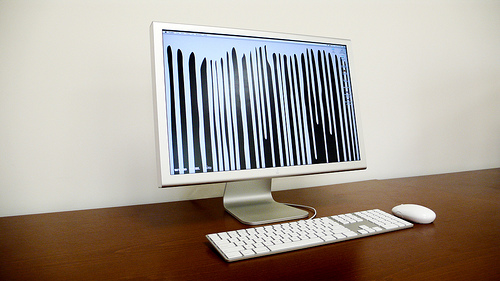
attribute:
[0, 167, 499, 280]
desk — long, wooden, brown, flat, wood surface, empty, rich brown color, wood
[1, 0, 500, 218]
wall — painted, cream colored, white, empty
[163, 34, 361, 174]
image — black, white, light blue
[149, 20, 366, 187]
screen — white, silver, on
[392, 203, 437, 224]
mouse — smooth, white, wireless, cordless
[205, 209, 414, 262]
keyboard — silver, flat, white, slim, metal, thin, minimal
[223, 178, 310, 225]
stand — silver, smooth, metal, metallic, grey, sleek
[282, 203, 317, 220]
cord — white, curved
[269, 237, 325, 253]
space bar key — white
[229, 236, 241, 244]
computer key — white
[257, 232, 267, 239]
computer key — white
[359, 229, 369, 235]
computer key — white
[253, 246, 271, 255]
computer key — white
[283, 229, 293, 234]
computer key — white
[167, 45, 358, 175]
lines — blue, black, white, light blue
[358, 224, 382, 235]
four keys — white, upside down t shape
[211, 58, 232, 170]
lines — thinner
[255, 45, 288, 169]
lines — longer